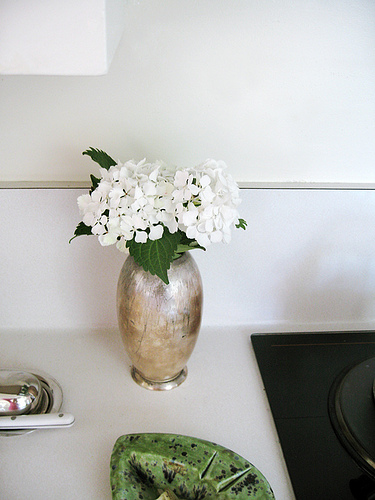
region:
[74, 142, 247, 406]
a vase is filled with flowers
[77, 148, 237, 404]
a metallic vase is on a counter top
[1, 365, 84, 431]
a dish containing flatware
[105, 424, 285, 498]
a green ceramic dish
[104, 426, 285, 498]
a ashtray is on a counter top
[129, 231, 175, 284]
part of a leaf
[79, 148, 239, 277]
a plant with green leaves and white flowers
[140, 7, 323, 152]
the wall is painted white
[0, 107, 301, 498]
several small items placed on a counter top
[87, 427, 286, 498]
a glazed clay ash tray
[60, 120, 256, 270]
white flowers and green leaves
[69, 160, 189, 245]
flower composed of connected white petals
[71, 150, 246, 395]
oval and silver vase holding flowers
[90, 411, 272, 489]
curved piece of ceramic with black spots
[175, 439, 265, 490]
two long indentations on rim of container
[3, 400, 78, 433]
white handle on a metal tray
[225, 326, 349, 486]
black panel on white surface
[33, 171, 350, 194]
edge along backsplash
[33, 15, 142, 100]
corner of white cube on wall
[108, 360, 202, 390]
small round base at bottom of vase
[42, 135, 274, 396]
a small silver vase holding white flowers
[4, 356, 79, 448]
a silver butter dish with a white knife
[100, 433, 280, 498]
a green and black speckled piece of ceramics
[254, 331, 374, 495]
the corner of a black stove top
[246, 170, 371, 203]
the edge of the white black splash of the counter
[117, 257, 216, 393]
the somewhat tarnished silver vase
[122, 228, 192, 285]
a green leaf coming out from the white flowers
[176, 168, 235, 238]
white flowers with tiny little petals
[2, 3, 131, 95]
the corner of a white cupboard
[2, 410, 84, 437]
the end of a white knife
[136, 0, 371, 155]
Part of a white wall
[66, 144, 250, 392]
White flowers in a vase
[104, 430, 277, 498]
A green spotted object sitting on a counter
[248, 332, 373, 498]
The edge of a black stove top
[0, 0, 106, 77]
The edge of a white cupboard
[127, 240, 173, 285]
A large green leaf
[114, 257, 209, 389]
A brown vase on a counter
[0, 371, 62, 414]
A silver object reflecting an image in the counter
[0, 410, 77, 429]
A long white object sticking out of a hole in the counter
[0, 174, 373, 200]
A white ledge behind the flowers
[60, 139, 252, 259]
White flowers in a vase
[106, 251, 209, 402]
vase of flowers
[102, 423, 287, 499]
Green containes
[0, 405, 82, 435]
White handle is on a container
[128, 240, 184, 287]
Leaves behind the flowers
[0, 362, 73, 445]
Container on a side table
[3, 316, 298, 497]
Side table is white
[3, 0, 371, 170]
Wall is white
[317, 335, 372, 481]
Chair with black border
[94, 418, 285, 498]
Container in form of leave